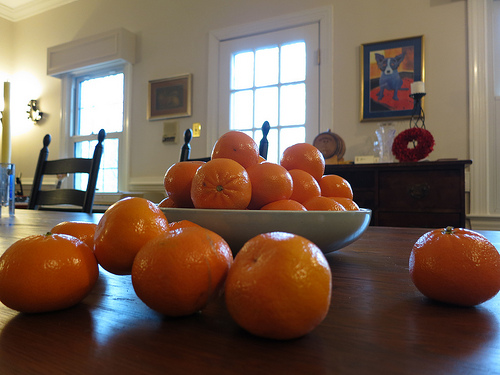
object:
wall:
[6, 1, 497, 235]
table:
[1, 198, 497, 373]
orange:
[404, 221, 497, 311]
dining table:
[1, 205, 498, 373]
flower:
[388, 126, 438, 166]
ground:
[405, 218, 467, 230]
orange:
[0, 230, 102, 315]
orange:
[189, 156, 252, 210]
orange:
[246, 160, 293, 203]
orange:
[282, 168, 323, 207]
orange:
[301, 194, 346, 212]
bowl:
[156, 205, 371, 254]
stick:
[404, 79, 426, 157]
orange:
[209, 132, 260, 171]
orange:
[161, 159, 211, 207]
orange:
[258, 197, 307, 211]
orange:
[318, 173, 353, 200]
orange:
[280, 141, 325, 182]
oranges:
[222, 228, 333, 340]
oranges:
[127, 218, 235, 316]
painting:
[360, 32, 427, 124]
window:
[65, 67, 132, 196]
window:
[221, 36, 313, 166]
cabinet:
[308, 151, 476, 232]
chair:
[24, 126, 113, 216]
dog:
[370, 50, 409, 100]